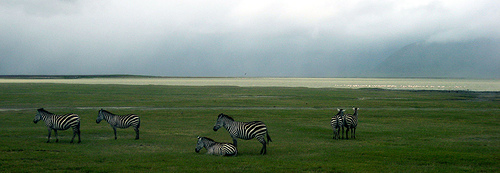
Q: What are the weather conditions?
A: It is clear.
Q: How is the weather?
A: It is clear.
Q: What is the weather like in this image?
A: It is clear.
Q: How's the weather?
A: It is clear.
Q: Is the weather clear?
A: Yes, it is clear.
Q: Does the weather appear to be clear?
A: Yes, it is clear.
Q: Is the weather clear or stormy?
A: It is clear.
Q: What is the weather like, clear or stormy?
A: It is clear.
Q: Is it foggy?
A: No, it is clear.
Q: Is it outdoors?
A: Yes, it is outdoors.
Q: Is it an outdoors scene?
A: Yes, it is outdoors.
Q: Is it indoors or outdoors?
A: It is outdoors.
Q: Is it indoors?
A: No, it is outdoors.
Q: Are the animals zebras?
A: No, there are both zebras and birds.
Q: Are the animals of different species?
A: Yes, they are zebras and birds.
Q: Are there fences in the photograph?
A: No, there are no fences.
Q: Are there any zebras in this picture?
A: Yes, there is a zebra.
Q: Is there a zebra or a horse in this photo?
A: Yes, there is a zebra.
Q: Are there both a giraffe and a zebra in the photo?
A: No, there is a zebra but no giraffes.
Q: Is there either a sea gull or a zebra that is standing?
A: Yes, the zebra is standing.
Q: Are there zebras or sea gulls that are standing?
A: Yes, the zebra is standing.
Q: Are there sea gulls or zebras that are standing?
A: Yes, the zebra is standing.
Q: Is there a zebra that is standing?
A: Yes, there is a zebra that is standing.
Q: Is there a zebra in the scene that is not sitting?
A: Yes, there is a zebra that is standing.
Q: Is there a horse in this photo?
A: No, there are no horses.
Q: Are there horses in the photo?
A: No, there are no horses.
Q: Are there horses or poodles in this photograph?
A: No, there are no horses or poodles.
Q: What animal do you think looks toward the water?
A: The zebra looks toward the water.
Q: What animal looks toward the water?
A: The zebra looks toward the water.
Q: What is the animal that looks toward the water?
A: The animal is a zebra.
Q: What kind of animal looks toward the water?
A: The animal is a zebra.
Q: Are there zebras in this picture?
A: Yes, there is a zebra.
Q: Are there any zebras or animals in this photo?
A: Yes, there is a zebra.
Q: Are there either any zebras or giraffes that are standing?
A: Yes, the zebra is standing.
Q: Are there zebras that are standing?
A: Yes, there is a zebra that is standing.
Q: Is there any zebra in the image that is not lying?
A: Yes, there is a zebra that is standing.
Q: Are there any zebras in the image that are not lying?
A: Yes, there is a zebra that is standing.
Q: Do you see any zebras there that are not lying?
A: Yes, there is a zebra that is standing .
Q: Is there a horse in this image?
A: No, there are no horses.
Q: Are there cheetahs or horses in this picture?
A: No, there are no horses or cheetahs.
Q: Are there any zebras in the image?
A: Yes, there is a zebra.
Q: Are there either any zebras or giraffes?
A: Yes, there is a zebra.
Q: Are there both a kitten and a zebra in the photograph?
A: No, there is a zebra but no kittens.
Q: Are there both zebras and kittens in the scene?
A: No, there is a zebra but no kittens.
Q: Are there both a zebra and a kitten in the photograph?
A: No, there is a zebra but no kittens.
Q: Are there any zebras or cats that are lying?
A: Yes, the zebra is lying.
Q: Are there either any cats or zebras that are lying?
A: Yes, the zebra is lying.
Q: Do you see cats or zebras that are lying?
A: Yes, the zebra is lying.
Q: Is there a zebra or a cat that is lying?
A: Yes, the zebra is lying.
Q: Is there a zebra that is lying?
A: Yes, there is a zebra that is lying.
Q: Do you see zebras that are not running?
A: Yes, there is a zebra that is lying .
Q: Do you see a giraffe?
A: No, there are no giraffes.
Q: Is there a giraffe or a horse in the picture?
A: No, there are no giraffes or horses.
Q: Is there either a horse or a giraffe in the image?
A: No, there are no giraffes or horses.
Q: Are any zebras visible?
A: Yes, there is a zebra.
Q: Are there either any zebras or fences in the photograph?
A: Yes, there is a zebra.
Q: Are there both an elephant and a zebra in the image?
A: No, there is a zebra but no elephants.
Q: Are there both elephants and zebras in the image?
A: No, there is a zebra but no elephants.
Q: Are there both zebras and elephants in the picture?
A: No, there is a zebra but no elephants.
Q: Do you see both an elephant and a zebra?
A: No, there is a zebra but no elephants.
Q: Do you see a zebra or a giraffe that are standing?
A: Yes, the zebra is standing.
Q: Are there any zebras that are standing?
A: Yes, there is a zebra that is standing.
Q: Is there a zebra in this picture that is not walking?
A: Yes, there is a zebra that is standing.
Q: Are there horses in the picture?
A: No, there are no horses.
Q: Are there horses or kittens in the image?
A: No, there are no horses or kittens.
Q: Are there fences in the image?
A: No, there are no fences.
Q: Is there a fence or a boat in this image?
A: No, there are no fences or boats.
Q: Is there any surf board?
A: No, there are no surfboards.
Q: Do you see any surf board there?
A: No, there are no surfboards.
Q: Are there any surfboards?
A: No, there are no surfboards.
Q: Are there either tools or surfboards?
A: No, there are no surfboards or tools.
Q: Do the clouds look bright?
A: Yes, the clouds are bright.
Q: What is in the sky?
A: The clouds are in the sky.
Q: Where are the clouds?
A: The clouds are in the sky.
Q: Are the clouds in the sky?
A: Yes, the clouds are in the sky.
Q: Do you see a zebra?
A: Yes, there is a zebra.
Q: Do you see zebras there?
A: Yes, there is a zebra.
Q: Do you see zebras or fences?
A: Yes, there is a zebra.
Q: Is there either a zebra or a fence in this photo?
A: Yes, there is a zebra.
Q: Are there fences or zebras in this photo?
A: Yes, there is a zebra.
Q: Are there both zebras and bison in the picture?
A: No, there is a zebra but no bison.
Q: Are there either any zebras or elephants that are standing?
A: Yes, the zebra is standing.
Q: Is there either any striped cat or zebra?
A: Yes, there is a striped zebra.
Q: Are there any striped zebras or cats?
A: Yes, there is a striped zebra.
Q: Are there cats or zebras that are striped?
A: Yes, the zebra is striped.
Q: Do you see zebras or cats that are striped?
A: Yes, the zebra is striped.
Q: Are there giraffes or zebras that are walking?
A: Yes, the zebra is walking.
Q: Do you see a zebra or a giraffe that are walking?
A: Yes, the zebra is walking.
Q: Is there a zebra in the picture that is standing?
A: Yes, there is a zebra that is standing.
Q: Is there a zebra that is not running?
A: Yes, there is a zebra that is standing.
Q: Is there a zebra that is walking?
A: Yes, there is a zebra that is walking.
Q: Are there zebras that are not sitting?
A: Yes, there is a zebra that is walking.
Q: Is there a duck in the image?
A: No, there are no ducks.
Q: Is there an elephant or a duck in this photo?
A: No, there are no ducks or elephants.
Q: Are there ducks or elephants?
A: No, there are no ducks or elephants.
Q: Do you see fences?
A: No, there are no fences.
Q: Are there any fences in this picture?
A: No, there are no fences.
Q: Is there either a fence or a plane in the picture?
A: No, there are no fences or airplanes.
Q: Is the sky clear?
A: Yes, the sky is clear.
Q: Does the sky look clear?
A: Yes, the sky is clear.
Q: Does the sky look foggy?
A: No, the sky is clear.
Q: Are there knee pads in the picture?
A: No, there are no knee pads.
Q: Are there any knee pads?
A: No, there are no knee pads.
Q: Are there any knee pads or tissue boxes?
A: No, there are no knee pads or tissue boxes.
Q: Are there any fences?
A: No, there are no fences.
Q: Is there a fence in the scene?
A: No, there are no fences.